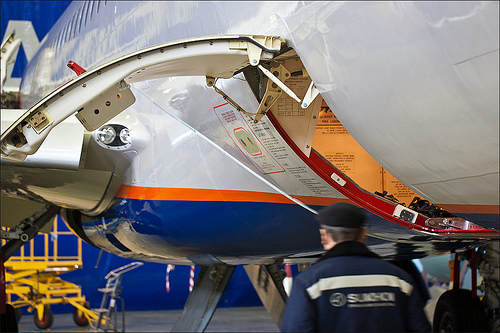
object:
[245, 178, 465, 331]
person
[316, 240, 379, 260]
collar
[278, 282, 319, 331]
arm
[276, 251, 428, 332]
jacket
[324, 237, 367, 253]
neck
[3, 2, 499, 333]
plane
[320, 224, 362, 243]
hair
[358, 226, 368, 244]
ear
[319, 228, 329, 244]
ear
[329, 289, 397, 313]
back